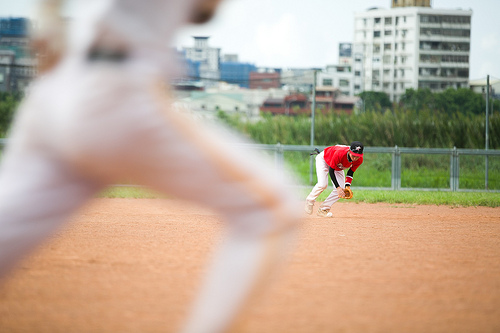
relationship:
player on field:
[299, 135, 372, 220] [0, 195, 500, 326]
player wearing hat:
[299, 135, 372, 220] [349, 139, 365, 156]